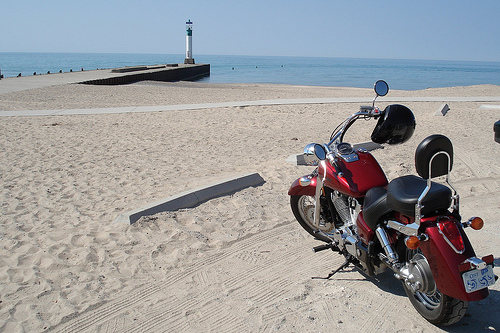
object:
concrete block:
[0, 115, 272, 333]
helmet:
[370, 104, 416, 146]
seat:
[386, 174, 453, 218]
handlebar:
[330, 105, 383, 143]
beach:
[0, 81, 500, 333]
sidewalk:
[0, 95, 500, 117]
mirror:
[314, 144, 327, 160]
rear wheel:
[402, 254, 467, 326]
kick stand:
[311, 259, 352, 279]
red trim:
[288, 150, 388, 197]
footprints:
[2, 116, 124, 333]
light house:
[184, 18, 195, 64]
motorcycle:
[287, 80, 499, 327]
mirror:
[374, 80, 390, 97]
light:
[468, 216, 484, 230]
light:
[404, 235, 420, 249]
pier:
[0, 63, 210, 85]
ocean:
[0, 0, 499, 85]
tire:
[290, 195, 336, 244]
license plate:
[462, 265, 498, 293]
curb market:
[123, 170, 268, 225]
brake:
[311, 242, 335, 254]